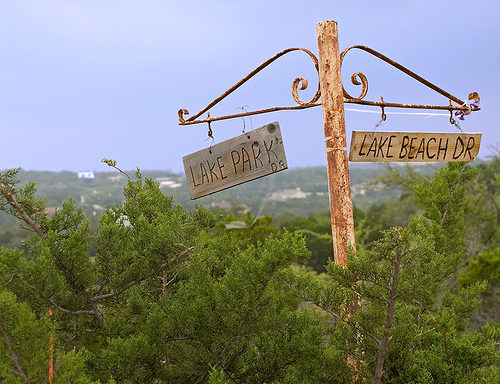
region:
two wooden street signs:
[181, 121, 483, 201]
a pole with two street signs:
[175, 19, 483, 382]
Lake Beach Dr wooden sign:
[349, 130, 481, 160]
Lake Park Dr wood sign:
[182, 120, 289, 198]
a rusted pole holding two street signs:
[177, 20, 482, 232]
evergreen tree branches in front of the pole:
[1, 158, 498, 382]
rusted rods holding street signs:
[177, 43, 482, 128]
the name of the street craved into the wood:
[185, 136, 285, 188]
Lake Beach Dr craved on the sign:
[348, 130, 482, 162]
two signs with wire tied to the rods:
[182, 98, 482, 201]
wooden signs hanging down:
[69, 32, 469, 322]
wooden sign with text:
[128, 111, 283, 221]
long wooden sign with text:
[305, 120, 480, 207]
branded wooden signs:
[171, 92, 493, 232]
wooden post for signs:
[302, 24, 362, 293]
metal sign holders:
[158, 27, 463, 127]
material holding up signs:
[181, 97, 273, 139]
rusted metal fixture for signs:
[155, 0, 379, 311]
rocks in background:
[217, 178, 323, 234]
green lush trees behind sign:
[9, 195, 280, 382]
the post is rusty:
[280, 12, 465, 363]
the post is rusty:
[290, 80, 397, 256]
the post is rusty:
[310, 13, 421, 280]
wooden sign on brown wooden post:
[348, 116, 494, 176]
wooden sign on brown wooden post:
[177, 130, 294, 200]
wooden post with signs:
[312, 35, 361, 277]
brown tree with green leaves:
[18, 255, 108, 374]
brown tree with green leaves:
[138, 219, 216, 287]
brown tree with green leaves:
[141, 277, 229, 348]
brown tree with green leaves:
[252, 239, 339, 354]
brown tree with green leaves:
[348, 268, 403, 351]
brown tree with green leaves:
[402, 270, 465, 372]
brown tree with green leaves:
[423, 199, 477, 302]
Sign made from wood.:
[342, 115, 492, 175]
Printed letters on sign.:
[342, 116, 497, 177]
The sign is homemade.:
[342, 106, 492, 171]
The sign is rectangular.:
[343, 115, 496, 182]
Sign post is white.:
[161, 10, 498, 382]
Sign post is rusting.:
[159, 5, 496, 380]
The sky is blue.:
[3, 2, 499, 170]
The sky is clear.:
[0, 0, 497, 164]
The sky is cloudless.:
[1, 2, 498, 168]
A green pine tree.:
[4, 161, 347, 381]